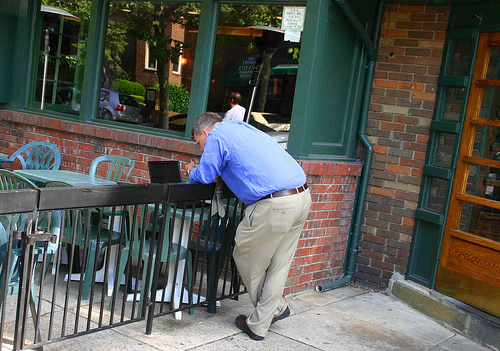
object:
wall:
[355, 6, 454, 282]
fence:
[0, 183, 255, 349]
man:
[185, 111, 312, 340]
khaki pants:
[232, 186, 313, 337]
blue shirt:
[188, 118, 307, 204]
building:
[3, 2, 500, 296]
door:
[432, 31, 500, 319]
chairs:
[10, 138, 63, 170]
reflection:
[57, 15, 272, 123]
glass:
[26, 3, 305, 137]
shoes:
[232, 313, 264, 341]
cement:
[8, 270, 450, 349]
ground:
[1, 284, 500, 350]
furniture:
[0, 138, 205, 302]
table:
[13, 167, 118, 188]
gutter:
[312, 4, 387, 294]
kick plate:
[432, 267, 500, 317]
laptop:
[146, 159, 204, 183]